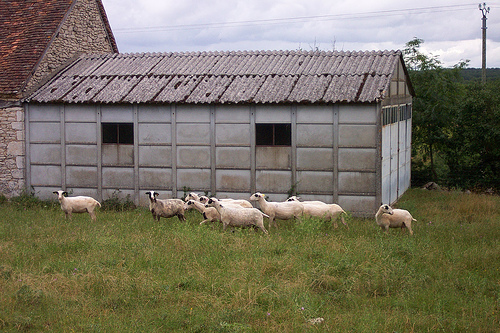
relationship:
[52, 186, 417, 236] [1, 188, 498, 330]
goats are in field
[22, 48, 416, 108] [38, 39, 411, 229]
roof on building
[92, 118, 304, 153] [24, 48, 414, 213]
openings on shed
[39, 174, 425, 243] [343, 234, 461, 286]
animals on grass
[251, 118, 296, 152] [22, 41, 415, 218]
window on building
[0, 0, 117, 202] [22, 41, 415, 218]
house connected building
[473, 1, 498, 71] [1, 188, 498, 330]
utility pole in field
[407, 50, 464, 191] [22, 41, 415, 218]
tree next to building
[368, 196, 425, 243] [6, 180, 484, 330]
animal on ground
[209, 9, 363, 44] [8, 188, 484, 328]
clouds above land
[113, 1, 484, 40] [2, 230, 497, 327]
wires above land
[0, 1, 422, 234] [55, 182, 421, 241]
building behind goats